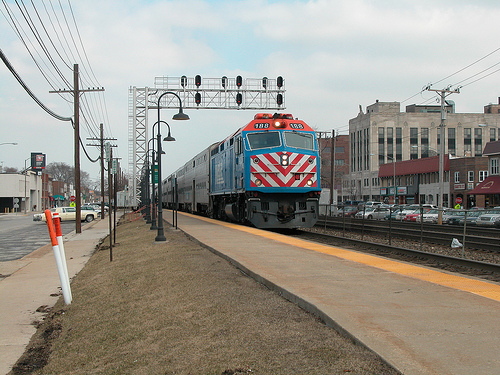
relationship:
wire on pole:
[71, 27, 88, 54] [61, 60, 93, 243]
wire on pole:
[58, 32, 71, 49] [61, 60, 93, 243]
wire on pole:
[43, 25, 62, 51] [61, 60, 93, 243]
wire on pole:
[34, 47, 55, 64] [61, 60, 93, 243]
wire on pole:
[28, 60, 49, 80] [61, 60, 93, 243]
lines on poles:
[41, 114, 126, 162] [1, 40, 128, 232]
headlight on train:
[272, 120, 282, 130] [152, 111, 323, 231]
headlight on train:
[281, 154, 288, 170] [152, 111, 323, 231]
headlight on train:
[306, 171, 318, 188] [163, 110, 343, 232]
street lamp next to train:
[155, 89, 188, 244] [152, 111, 323, 231]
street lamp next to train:
[149, 120, 173, 231] [152, 111, 323, 231]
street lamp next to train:
[146, 133, 164, 228] [152, 111, 323, 231]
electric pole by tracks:
[429, 82, 455, 223] [214, 217, 497, 283]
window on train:
[245, 130, 282, 150] [152, 111, 323, 231]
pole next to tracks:
[322, 125, 339, 212] [274, 217, 496, 288]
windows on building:
[403, 116, 423, 167] [338, 84, 498, 195]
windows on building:
[367, 107, 388, 164] [338, 84, 498, 195]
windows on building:
[468, 123, 490, 160] [338, 84, 498, 195]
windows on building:
[438, 119, 460, 161] [338, 84, 498, 195]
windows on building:
[414, 116, 434, 167] [338, 84, 498, 195]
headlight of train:
[272, 120, 282, 130] [152, 111, 323, 231]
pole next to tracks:
[61, 70, 132, 259] [315, 206, 497, 282]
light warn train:
[277, 92, 285, 109] [152, 111, 323, 231]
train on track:
[152, 111, 323, 231] [304, 230, 499, 280]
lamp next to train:
[151, 82, 186, 264] [152, 111, 323, 231]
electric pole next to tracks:
[49, 63, 104, 233] [283, 227, 497, 284]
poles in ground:
[40, 207, 80, 314] [57, 307, 222, 368]